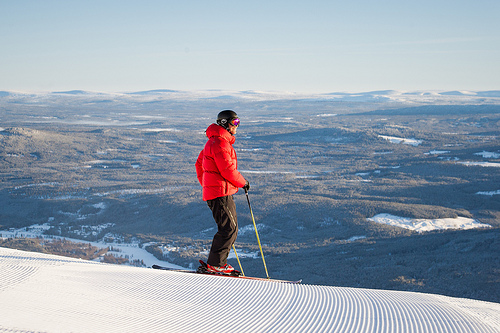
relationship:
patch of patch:
[364, 211, 491, 236] [367, 211, 494, 233]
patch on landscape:
[367, 211, 494, 233] [2, 87, 497, 304]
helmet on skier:
[217, 107, 252, 149] [180, 88, 278, 290]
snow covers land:
[374, 196, 474, 238] [325, 193, 493, 261]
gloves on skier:
[240, 180, 251, 191] [194, 106, 253, 276]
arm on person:
[215, 130, 250, 191] [198, 111, 248, 279]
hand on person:
[238, 180, 254, 194] [174, 116, 311, 306]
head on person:
[217, 107, 239, 136] [182, 107, 262, 283]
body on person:
[191, 123, 238, 260] [184, 100, 246, 277]